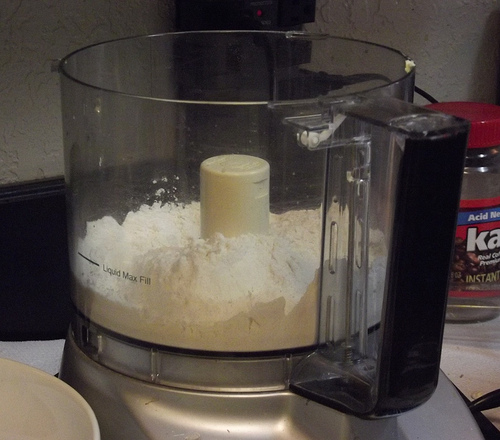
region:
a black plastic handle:
[334, 118, 471, 416]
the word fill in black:
[137, 273, 152, 285]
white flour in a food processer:
[58, 22, 476, 439]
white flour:
[78, 190, 388, 352]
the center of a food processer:
[191, 151, 278, 248]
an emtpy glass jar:
[413, 97, 499, 322]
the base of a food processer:
[57, 324, 491, 438]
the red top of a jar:
[417, 101, 499, 150]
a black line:
[77, 250, 101, 270]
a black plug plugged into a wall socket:
[249, 46, 386, 101]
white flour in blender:
[58, 23, 466, 433]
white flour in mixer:
[56, 22, 475, 439]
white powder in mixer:
[53, 24, 474, 436]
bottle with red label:
[445, 107, 497, 324]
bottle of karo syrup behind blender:
[443, 89, 499, 329]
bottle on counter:
[438, 90, 498, 330]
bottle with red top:
[443, 89, 498, 329]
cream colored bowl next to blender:
[3, 340, 103, 438]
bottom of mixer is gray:
[50, 325, 391, 438]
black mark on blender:
[70, 239, 152, 301]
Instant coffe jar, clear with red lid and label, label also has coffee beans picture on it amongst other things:
[411, 100, 496, 327]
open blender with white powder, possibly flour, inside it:
[58, 26, 440, 438]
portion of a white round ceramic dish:
[2, 350, 101, 437]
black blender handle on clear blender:
[286, 101, 468, 420]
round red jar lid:
[417, 99, 496, 151]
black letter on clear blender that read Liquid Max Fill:
[100, 263, 153, 289]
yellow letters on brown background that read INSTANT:
[465, 272, 498, 284]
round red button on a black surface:
[253, 6, 265, 19]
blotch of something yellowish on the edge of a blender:
[403, 57, 415, 75]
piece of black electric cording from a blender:
[466, 389, 498, 416]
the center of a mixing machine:
[197, 150, 274, 242]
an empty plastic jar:
[413, 96, 498, 323]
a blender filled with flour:
[53, 35, 468, 424]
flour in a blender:
[85, 221, 320, 336]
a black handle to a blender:
[349, 105, 460, 400]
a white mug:
[0, 333, 113, 438]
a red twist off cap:
[423, 102, 499, 147]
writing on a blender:
[95, 262, 153, 294]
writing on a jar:
[465, 223, 498, 258]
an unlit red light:
[253, 7, 262, 16]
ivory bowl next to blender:
[5, 339, 100, 438]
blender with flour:
[49, 32, 488, 435]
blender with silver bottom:
[60, 34, 465, 437]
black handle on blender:
[324, 88, 471, 420]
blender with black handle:
[64, 43, 466, 433]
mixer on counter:
[53, 38, 491, 438]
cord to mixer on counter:
[460, 365, 499, 422]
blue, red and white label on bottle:
[448, 198, 499, 299]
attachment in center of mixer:
[197, 147, 271, 245]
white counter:
[441, 307, 498, 406]